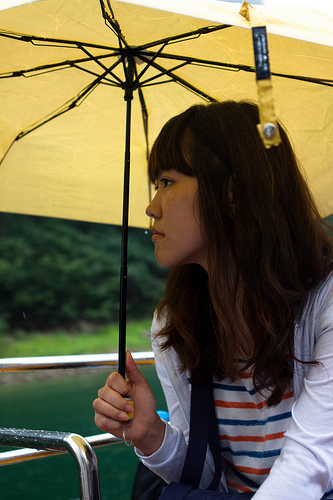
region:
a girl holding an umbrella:
[0, 1, 327, 496]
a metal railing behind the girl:
[0, 350, 168, 471]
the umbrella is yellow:
[0, 0, 331, 230]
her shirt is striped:
[196, 352, 295, 495]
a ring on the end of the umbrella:
[120, 421, 137, 445]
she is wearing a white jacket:
[141, 294, 328, 498]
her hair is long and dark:
[128, 106, 331, 407]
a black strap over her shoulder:
[171, 295, 229, 494]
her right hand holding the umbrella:
[79, 262, 208, 496]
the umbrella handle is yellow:
[117, 392, 137, 424]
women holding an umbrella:
[102, 359, 160, 441]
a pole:
[68, 434, 113, 492]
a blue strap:
[187, 421, 213, 440]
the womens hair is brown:
[213, 261, 290, 355]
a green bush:
[6, 230, 122, 307]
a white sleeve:
[289, 420, 329, 490]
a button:
[263, 122, 278, 139]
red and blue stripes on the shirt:
[218, 401, 271, 462]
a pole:
[21, 354, 52, 375]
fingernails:
[117, 408, 128, 420]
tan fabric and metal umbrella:
[2, 2, 332, 229]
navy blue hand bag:
[160, 483, 255, 499]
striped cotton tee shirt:
[195, 349, 297, 481]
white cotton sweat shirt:
[139, 274, 331, 499]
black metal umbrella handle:
[117, 62, 131, 425]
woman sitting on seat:
[96, 100, 332, 499]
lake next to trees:
[3, 364, 163, 498]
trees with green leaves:
[2, 213, 163, 340]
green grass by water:
[2, 318, 154, 359]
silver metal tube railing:
[0, 352, 161, 466]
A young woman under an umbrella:
[26, 103, 329, 456]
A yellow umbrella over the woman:
[5, 0, 332, 213]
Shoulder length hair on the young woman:
[143, 115, 321, 388]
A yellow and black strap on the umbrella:
[230, 22, 294, 153]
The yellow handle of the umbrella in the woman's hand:
[112, 392, 142, 446]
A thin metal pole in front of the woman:
[11, 420, 111, 499]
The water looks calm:
[34, 391, 85, 431]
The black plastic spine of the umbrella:
[42, 12, 178, 243]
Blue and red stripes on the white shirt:
[213, 390, 308, 458]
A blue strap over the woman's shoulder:
[167, 318, 230, 498]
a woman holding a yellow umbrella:
[1, 1, 332, 499]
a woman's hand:
[93, 349, 154, 447]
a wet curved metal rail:
[0, 426, 100, 498]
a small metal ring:
[121, 425, 133, 445]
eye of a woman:
[158, 176, 176, 187]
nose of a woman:
[144, 194, 163, 218]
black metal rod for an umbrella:
[117, 54, 135, 374]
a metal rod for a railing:
[1, 351, 154, 371]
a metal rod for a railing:
[0, 433, 116, 467]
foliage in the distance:
[0, 213, 166, 337]